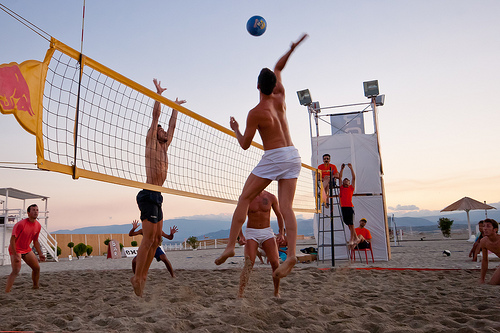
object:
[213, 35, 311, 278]
man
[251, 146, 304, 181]
shorts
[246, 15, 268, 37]
ball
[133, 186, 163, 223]
shorts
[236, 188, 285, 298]
man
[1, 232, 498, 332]
sand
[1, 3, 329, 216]
net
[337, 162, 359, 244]
man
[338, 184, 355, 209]
shirt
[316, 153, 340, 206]
referee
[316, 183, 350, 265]
chair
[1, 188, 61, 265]
life guard stand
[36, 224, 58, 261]
ladder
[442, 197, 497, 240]
umbrella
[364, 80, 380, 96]
flood light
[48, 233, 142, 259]
barrier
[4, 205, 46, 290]
man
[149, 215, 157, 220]
logo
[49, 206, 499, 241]
mountain range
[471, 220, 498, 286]
man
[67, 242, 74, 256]
plant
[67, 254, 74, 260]
pot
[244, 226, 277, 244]
shorts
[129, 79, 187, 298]
man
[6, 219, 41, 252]
t-shirt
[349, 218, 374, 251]
man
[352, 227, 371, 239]
shirt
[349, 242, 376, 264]
chair